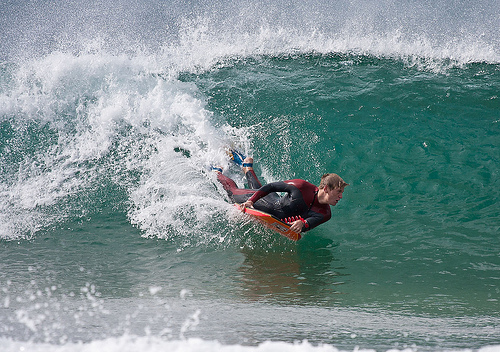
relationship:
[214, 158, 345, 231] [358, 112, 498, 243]
man in water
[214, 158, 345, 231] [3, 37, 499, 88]
man on waves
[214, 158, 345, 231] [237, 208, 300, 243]
man on surf board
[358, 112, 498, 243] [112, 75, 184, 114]
water has foam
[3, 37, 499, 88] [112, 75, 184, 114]
waves have foam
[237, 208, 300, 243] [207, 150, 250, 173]
surf board has footstraps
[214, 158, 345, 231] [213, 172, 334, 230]
man wearing wet suit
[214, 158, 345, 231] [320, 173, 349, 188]
man has hair